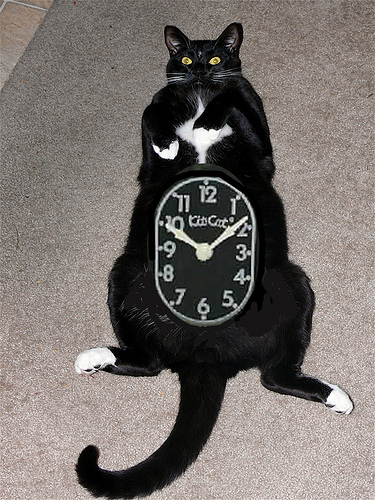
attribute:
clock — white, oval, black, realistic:
[156, 177, 257, 324]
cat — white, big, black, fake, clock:
[77, 20, 353, 499]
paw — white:
[193, 116, 223, 143]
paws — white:
[152, 124, 222, 166]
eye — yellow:
[206, 53, 224, 67]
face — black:
[167, 42, 240, 89]